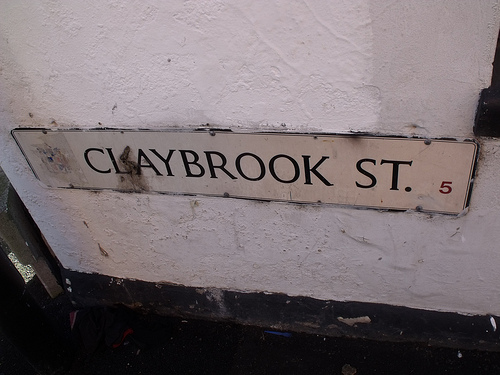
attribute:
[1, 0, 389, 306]
stucco — white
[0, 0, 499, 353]
wall — white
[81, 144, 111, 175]
letter — black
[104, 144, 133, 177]
letter — black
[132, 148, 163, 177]
letter — black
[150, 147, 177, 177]
letter — black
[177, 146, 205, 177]
letter — black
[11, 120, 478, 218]
sign — rectangular, white, square, old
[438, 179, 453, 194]
number — red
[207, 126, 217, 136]
screw — metal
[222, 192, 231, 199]
screw — metal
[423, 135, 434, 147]
screw — metal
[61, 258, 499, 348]
strip — black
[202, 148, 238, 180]
letter — black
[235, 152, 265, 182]
letter — black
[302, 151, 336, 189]
letter — black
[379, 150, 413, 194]
letter — black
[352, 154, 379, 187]
letter — black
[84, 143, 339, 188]
word — black